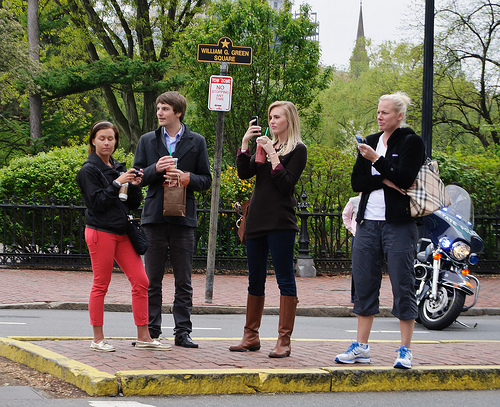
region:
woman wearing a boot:
[229, 96, 314, 361]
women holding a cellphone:
[235, 97, 310, 354]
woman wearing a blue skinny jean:
[227, 93, 307, 365]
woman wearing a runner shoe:
[327, 87, 433, 367]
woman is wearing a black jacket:
[318, 87, 441, 373]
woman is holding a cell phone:
[327, 77, 436, 367]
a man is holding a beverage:
[121, 92, 210, 347]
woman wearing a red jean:
[69, 121, 156, 361]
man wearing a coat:
[127, 96, 215, 350]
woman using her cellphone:
[65, 113, 177, 364]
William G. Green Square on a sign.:
[192, 31, 259, 73]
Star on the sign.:
[209, 31, 246, 50]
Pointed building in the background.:
[350, 0, 380, 76]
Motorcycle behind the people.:
[334, 155, 487, 330]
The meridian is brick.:
[66, 331, 499, 373]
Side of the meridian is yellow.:
[112, 354, 498, 404]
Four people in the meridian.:
[70, 93, 437, 368]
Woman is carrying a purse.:
[394, 157, 454, 219]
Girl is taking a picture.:
[244, 111, 261, 140]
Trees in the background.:
[9, 1, 496, 225]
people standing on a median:
[66, 69, 441, 386]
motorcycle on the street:
[411, 181, 490, 346]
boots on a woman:
[221, 278, 305, 365]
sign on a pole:
[191, 43, 256, 315]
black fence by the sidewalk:
[7, 191, 79, 266]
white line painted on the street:
[6, 315, 32, 333]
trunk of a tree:
[21, 5, 78, 150]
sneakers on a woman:
[325, 338, 427, 370]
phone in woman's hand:
[244, 108, 267, 142]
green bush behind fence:
[316, 144, 351, 209]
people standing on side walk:
[9, 66, 481, 383]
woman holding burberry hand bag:
[367, 140, 466, 232]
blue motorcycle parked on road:
[388, 142, 498, 334]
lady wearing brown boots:
[223, 275, 317, 382]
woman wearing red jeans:
[64, 200, 185, 342]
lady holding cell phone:
[234, 105, 291, 195]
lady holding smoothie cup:
[245, 110, 277, 195]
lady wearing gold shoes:
[75, 320, 201, 355]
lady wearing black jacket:
[53, 126, 166, 244]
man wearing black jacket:
[120, 78, 220, 254]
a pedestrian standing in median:
[75, 120, 171, 350]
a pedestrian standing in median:
[131, 90, 211, 349]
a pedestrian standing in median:
[227, 100, 307, 356]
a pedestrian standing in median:
[335, 93, 450, 368]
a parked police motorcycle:
[411, 184, 480, 329]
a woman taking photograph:
[229, 101, 306, 356]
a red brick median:
[0, 333, 499, 395]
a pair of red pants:
[84, 226, 149, 324]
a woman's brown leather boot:
[268, 295, 295, 357]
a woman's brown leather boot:
[228, 293, 265, 350]